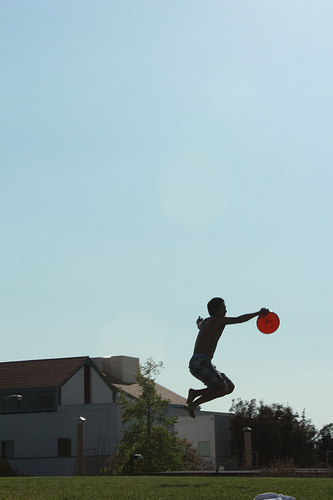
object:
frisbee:
[255, 311, 280, 333]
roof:
[1, 355, 119, 393]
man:
[184, 296, 270, 420]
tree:
[100, 353, 191, 473]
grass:
[1, 472, 332, 499]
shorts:
[188, 354, 228, 389]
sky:
[0, 0, 332, 445]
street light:
[1, 392, 23, 403]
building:
[0, 354, 203, 472]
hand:
[258, 306, 271, 317]